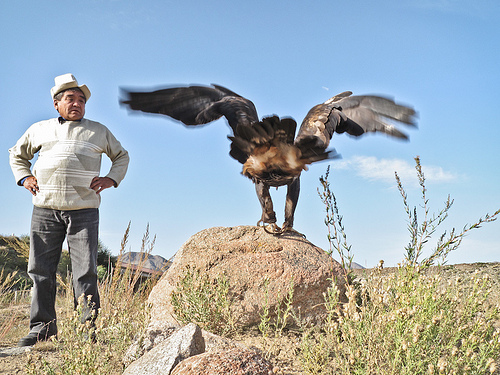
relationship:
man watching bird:
[7, 74, 128, 347] [118, 81, 418, 232]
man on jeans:
[7, 74, 128, 347] [25, 202, 100, 333]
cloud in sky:
[326, 147, 456, 193] [3, 1, 497, 270]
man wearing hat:
[7, 74, 128, 347] [44, 68, 95, 98]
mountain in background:
[339, 258, 369, 274] [112, 208, 498, 260]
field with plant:
[5, 255, 498, 372] [320, 227, 498, 364]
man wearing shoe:
[7, 74, 128, 347] [14, 325, 59, 347]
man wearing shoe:
[7, 74, 128, 347] [78, 319, 96, 346]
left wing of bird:
[116, 80, 254, 137] [162, 72, 322, 202]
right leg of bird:
[280, 181, 306, 228] [92, 67, 434, 210]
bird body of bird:
[235, 128, 307, 182] [118, 81, 418, 232]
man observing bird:
[12, 60, 132, 346] [108, 54, 435, 249]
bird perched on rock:
[142, 70, 412, 246] [125, 221, 364, 343]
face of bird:
[243, 143, 295, 183] [118, 81, 418, 232]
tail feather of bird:
[244, 119, 312, 186] [115, 59, 420, 239]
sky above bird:
[3, 1, 497, 270] [97, 60, 445, 255]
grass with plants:
[336, 300, 388, 355] [192, 285, 282, 358]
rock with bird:
[144, 224, 352, 332] [118, 81, 418, 232]